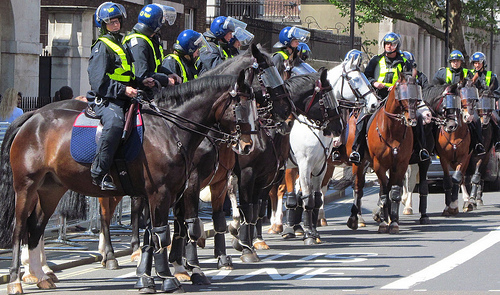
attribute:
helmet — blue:
[94, 1, 131, 27]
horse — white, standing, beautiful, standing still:
[286, 50, 380, 251]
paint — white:
[116, 245, 380, 283]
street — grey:
[1, 165, 500, 295]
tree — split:
[331, 0, 499, 71]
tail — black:
[1, 109, 30, 251]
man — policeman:
[89, 0, 145, 191]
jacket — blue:
[86, 33, 137, 101]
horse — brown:
[1, 69, 260, 294]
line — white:
[372, 219, 500, 293]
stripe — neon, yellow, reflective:
[124, 32, 163, 72]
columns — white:
[392, 31, 500, 93]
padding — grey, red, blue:
[68, 105, 149, 169]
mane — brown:
[147, 72, 240, 106]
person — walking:
[2, 88, 26, 125]